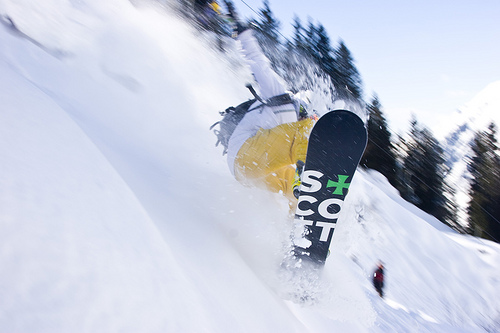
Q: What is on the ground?
A: Snow.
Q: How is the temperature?
A: Cold.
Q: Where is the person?
A: In the mountains.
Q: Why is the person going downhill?
A: Snowboarding.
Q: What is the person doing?
A: Snowboarding.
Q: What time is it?
A: Afternoon.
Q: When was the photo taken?
A: During the daytime.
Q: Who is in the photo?
A: A snowboarder.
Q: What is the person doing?
A: Snowboarding.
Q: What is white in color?
A: The snow.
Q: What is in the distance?
A: Some trees.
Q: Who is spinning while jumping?
A: Snowboarder.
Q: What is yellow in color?
A: The pants.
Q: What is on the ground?
A: Snow.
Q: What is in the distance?
A: Trees.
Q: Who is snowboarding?
A: A person.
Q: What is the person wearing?
A: A snowsuit.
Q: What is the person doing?
A: Riding a board.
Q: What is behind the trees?
A: Mountains.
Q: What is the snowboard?
A: Black.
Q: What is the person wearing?
A: Snow suit.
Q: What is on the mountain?
A: Snow.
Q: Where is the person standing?
A: Snow.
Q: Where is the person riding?
A: Mountain.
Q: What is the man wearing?
A: Jacekt.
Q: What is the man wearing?
A: Pants.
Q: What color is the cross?
A: Green.